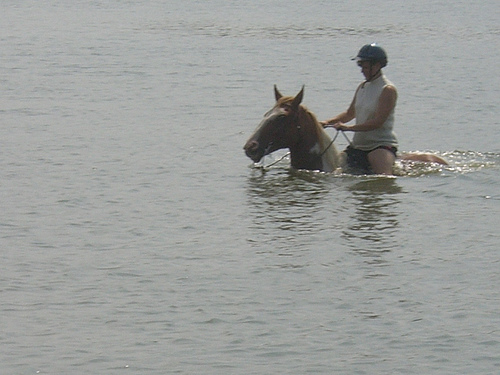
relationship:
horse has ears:
[239, 80, 457, 195] [271, 82, 306, 108]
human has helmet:
[316, 41, 399, 178] [350, 41, 389, 89]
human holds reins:
[316, 41, 399, 178] [317, 111, 349, 143]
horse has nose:
[239, 80, 457, 195] [234, 140, 272, 165]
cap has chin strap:
[348, 43, 396, 64] [358, 70, 382, 80]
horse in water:
[241, 83, 449, 175] [3, 2, 495, 372]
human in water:
[316, 41, 399, 178] [3, 2, 495, 372]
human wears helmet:
[316, 41, 399, 178] [349, 43, 387, 64]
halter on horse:
[294, 111, 354, 164] [238, 86, 470, 181]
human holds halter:
[316, 41, 399, 178] [319, 121, 354, 156]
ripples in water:
[254, 149, 498, 180] [3, 2, 495, 372]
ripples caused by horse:
[254, 149, 498, 180] [239, 80, 457, 195]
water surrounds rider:
[259, 199, 385, 269] [340, 39, 397, 118]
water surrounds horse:
[259, 199, 385, 269] [239, 80, 457, 195]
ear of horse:
[294, 85, 305, 107] [210, 77, 340, 198]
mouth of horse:
[246, 142, 265, 158] [240, 82, 482, 198]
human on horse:
[316, 41, 399, 178] [249, 85, 455, 175]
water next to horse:
[231, 187, 393, 247] [241, 83, 449, 175]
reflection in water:
[242, 165, 423, 262] [69, 203, 472, 311]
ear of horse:
[294, 85, 305, 107] [225, 73, 337, 157]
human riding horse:
[316, 41, 399, 178] [239, 80, 457, 195]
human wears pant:
[316, 41, 408, 179] [346, 144, 398, 169]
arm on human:
[336, 85, 400, 132] [316, 41, 399, 178]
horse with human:
[241, 83, 449, 175] [316, 41, 399, 178]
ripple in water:
[196, 188, 338, 268] [31, 10, 498, 340]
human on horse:
[316, 41, 399, 178] [242, 84, 449, 198]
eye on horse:
[276, 113, 288, 123] [246, 88, 356, 177]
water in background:
[113, 31, 325, 82] [14, 13, 484, 86]